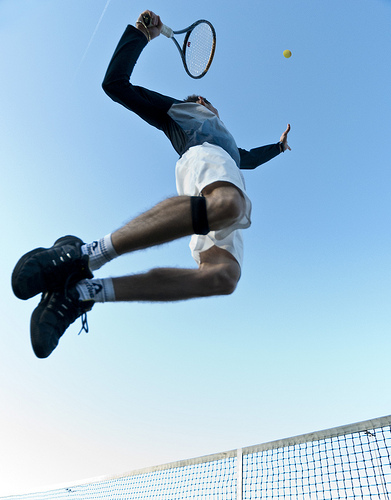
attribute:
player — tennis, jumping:
[13, 12, 291, 360]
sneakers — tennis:
[13, 233, 92, 358]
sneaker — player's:
[11, 238, 93, 304]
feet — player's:
[11, 224, 97, 365]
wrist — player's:
[129, 14, 159, 43]